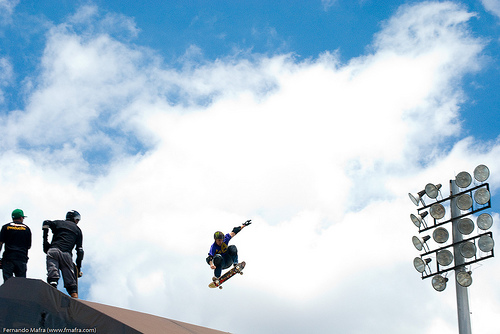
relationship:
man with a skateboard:
[204, 217, 255, 283] [191, 258, 250, 290]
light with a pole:
[403, 188, 423, 207] [441, 170, 476, 332]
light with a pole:
[419, 174, 444, 200] [441, 170, 476, 332]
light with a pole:
[447, 162, 477, 193] [441, 170, 476, 332]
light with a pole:
[471, 157, 496, 185] [441, 170, 476, 332]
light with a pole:
[427, 226, 452, 246] [441, 170, 476, 332]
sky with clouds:
[4, 3, 496, 333] [200, 94, 363, 192]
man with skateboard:
[42, 209, 85, 298] [72, 261, 78, 279]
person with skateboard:
[6, 207, 33, 292] [72, 261, 78, 279]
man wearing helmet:
[42, 209, 85, 298] [65, 206, 85, 224]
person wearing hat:
[6, 207, 33, 292] [6, 202, 28, 219]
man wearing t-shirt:
[204, 217, 255, 283] [206, 241, 238, 266]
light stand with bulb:
[373, 146, 498, 296] [472, 161, 485, 182]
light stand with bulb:
[373, 146, 498, 296] [471, 237, 496, 250]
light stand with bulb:
[373, 146, 498, 296] [429, 274, 444, 294]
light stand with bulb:
[373, 146, 498, 296] [411, 230, 426, 250]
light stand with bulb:
[373, 146, 498, 296] [431, 228, 446, 240]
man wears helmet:
[42, 209, 85, 298] [62, 205, 84, 220]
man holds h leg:
[203, 217, 265, 285] [211, 254, 228, 282]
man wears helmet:
[42, 209, 84, 293] [64, 204, 78, 219]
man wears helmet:
[204, 217, 255, 283] [212, 228, 223, 246]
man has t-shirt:
[204, 217, 255, 283] [208, 233, 234, 263]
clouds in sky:
[200, 76, 337, 173] [259, 9, 334, 55]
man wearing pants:
[42, 209, 85, 298] [0, 242, 82, 299]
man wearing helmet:
[204, 217, 255, 283] [209, 231, 229, 240]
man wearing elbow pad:
[204, 217, 255, 283] [231, 226, 242, 235]